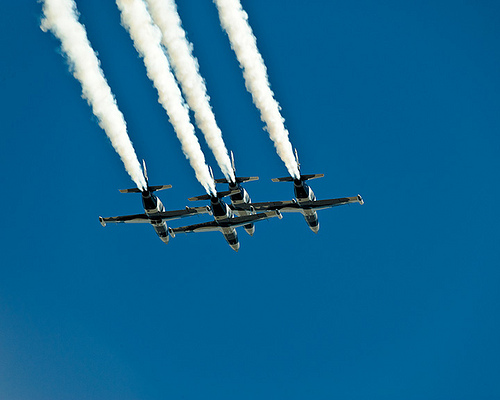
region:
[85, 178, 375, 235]
jets in the air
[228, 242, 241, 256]
nose of the jet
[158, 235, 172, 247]
nose of the jet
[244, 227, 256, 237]
nose of the jet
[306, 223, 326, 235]
nose of the jet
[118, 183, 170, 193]
tail of the jet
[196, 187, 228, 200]
tail of the jet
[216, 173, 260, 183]
tail of the jet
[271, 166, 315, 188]
tail of the jet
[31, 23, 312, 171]
smoke coming from jets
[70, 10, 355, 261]
planes flying in formation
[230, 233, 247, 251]
planes have white noses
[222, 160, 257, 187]
blue and white tails on planes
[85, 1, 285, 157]
white trails from planes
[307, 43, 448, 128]
sky is blue and clear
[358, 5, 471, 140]
no clouds in sky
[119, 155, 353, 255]
four planes close together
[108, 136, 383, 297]
planes are doing tricks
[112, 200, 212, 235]
narrow wings on planes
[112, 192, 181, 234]
thin wings on planes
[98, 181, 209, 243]
Airplane flying in the sky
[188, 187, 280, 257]
Second airplane flying in the sky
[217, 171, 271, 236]
Third airplane flying in the sky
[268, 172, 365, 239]
Fourth Airplane flying in the sky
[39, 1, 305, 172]
Condensation trails from airplanes flying in the sky.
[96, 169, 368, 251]
Airplanes flying in the sky.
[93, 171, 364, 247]
Airplanes flying in the sky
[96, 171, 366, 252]
Airplanes flying in the Sky.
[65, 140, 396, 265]
the planes are flying in formation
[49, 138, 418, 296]
four planes flying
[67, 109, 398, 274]
planes flying in the sky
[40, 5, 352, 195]
white jet smoke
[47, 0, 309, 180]
white smoke from the planes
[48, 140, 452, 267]
there are four planes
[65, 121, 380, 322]
the planes are white and black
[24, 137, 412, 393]
the sky is blue and clear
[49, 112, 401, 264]
all the planes are flying in the same direction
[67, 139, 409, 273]
the planes are flying together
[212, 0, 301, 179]
White contrail coming out of plane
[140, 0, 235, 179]
White contrail coming out of plane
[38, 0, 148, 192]
White contrail coming out of plane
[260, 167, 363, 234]
White and green plane flying in sky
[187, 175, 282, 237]
White and green plane flying in sky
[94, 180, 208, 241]
White and green plane flying in sky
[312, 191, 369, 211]
Long wing on airplane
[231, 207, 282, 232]
Long wing on airplane